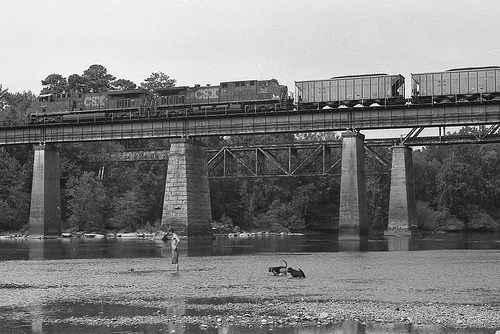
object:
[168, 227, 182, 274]
boy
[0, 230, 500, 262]
river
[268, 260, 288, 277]
dogs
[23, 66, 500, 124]
train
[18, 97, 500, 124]
tracks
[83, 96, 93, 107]
letters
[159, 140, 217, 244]
pillar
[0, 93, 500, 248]
bridge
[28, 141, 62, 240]
pillar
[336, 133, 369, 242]
pillar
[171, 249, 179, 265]
shorts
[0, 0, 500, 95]
sky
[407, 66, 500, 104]
cars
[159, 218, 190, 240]
mark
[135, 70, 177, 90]
trees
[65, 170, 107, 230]
bush